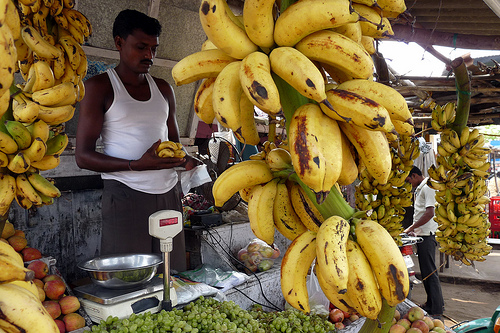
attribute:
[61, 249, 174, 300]
bowl — metal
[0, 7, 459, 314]
stand — selling fruit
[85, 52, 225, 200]
mans shirt — white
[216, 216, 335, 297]
fruit — Delicious